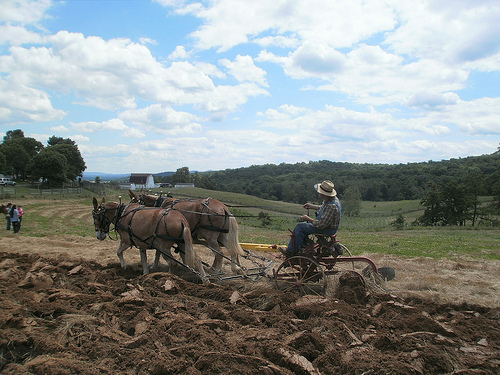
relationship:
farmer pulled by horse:
[278, 181, 344, 256] [89, 196, 208, 285]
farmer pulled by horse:
[278, 181, 344, 256] [124, 191, 247, 271]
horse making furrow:
[89, 196, 208, 285] [170, 287, 477, 348]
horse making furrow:
[89, 196, 208, 285] [0, 252, 84, 272]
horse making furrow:
[124, 191, 247, 271] [170, 287, 477, 348]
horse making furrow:
[124, 191, 247, 271] [0, 252, 84, 272]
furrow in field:
[170, 287, 477, 348] [6, 250, 499, 373]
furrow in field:
[0, 252, 84, 272] [6, 250, 499, 373]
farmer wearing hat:
[278, 181, 344, 256] [312, 181, 337, 195]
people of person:
[9, 205, 19, 234] [2, 196, 12, 228]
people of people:
[9, 205, 19, 234] [9, 205, 19, 234]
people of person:
[9, 205, 19, 234] [14, 200, 26, 230]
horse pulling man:
[91, 196, 207, 274] [277, 181, 342, 273]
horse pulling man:
[128, 189, 248, 273] [277, 181, 342, 273]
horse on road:
[91, 196, 207, 274] [3, 233, 495, 305]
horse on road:
[128, 189, 248, 273] [3, 233, 495, 305]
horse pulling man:
[91, 196, 207, 274] [289, 178, 344, 271]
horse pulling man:
[128, 189, 248, 273] [289, 178, 344, 271]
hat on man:
[310, 179, 345, 200] [269, 180, 343, 265]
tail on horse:
[180, 223, 197, 273] [91, 182, 209, 280]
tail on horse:
[223, 213, 245, 259] [127, 189, 247, 286]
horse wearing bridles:
[128, 189, 248, 273] [106, 193, 168, 242]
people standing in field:
[2, 200, 23, 236] [0, 187, 496, 372]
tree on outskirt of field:
[341, 186, 364, 218] [17, 200, 415, 328]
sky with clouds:
[0, 0, 500, 174] [0, 1, 497, 184]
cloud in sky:
[0, 1, 498, 121] [1, 5, 491, 160]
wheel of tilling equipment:
[273, 253, 327, 306] [269, 210, 397, 294]